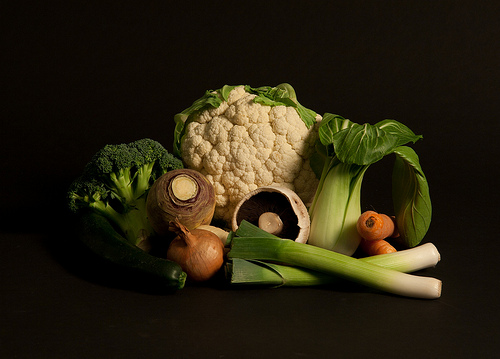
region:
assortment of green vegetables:
[43, 36, 468, 326]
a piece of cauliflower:
[168, 74, 325, 207]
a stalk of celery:
[236, 214, 446, 302]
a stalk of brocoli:
[62, 140, 187, 253]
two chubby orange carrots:
[356, 200, 398, 259]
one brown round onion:
[159, 212, 224, 293]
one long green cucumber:
[46, 209, 201, 311]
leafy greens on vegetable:
[316, 110, 441, 250]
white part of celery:
[389, 238, 456, 305]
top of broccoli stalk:
[68, 135, 178, 180]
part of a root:
[404, 290, 411, 295]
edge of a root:
[316, 216, 328, 249]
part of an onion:
[206, 256, 218, 263]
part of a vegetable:
[400, 182, 407, 200]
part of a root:
[201, 158, 220, 191]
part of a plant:
[320, 180, 332, 197]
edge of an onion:
[202, 255, 209, 263]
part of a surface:
[241, 314, 260, 324]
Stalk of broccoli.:
[63, 137, 195, 283]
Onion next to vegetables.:
[164, 217, 226, 284]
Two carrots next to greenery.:
[355, 200, 400, 262]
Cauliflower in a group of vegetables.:
[174, 88, 314, 208]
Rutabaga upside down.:
[154, 165, 223, 242]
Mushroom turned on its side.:
[233, 177, 315, 256]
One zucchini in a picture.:
[73, 185, 194, 293]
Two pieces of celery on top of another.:
[231, 221, 450, 305]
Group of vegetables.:
[44, 88, 449, 304]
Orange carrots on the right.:
[358, 193, 429, 276]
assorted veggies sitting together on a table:
[51, 82, 447, 309]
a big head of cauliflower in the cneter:
[174, 88, 311, 202]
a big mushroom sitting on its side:
[232, 183, 309, 248]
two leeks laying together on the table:
[218, 224, 443, 305]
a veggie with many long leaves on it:
[308, 108, 426, 263]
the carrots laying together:
[357, 209, 405, 258]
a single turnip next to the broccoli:
[150, 170, 212, 222]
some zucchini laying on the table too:
[73, 193, 189, 288]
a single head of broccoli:
[62, 133, 178, 240]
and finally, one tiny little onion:
[161, 223, 226, 273]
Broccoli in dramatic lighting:
[70, 147, 177, 235]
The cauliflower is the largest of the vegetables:
[165, 87, 327, 212]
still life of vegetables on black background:
[35, 50, 479, 344]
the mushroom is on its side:
[230, 184, 314, 246]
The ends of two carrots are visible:
[355, 200, 396, 260]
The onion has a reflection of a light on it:
[155, 211, 230, 281]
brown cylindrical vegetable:
[147, 168, 220, 230]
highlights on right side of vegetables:
[287, 67, 454, 313]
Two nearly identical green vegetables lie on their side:
[224, 215, 456, 312]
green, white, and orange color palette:
[70, 76, 449, 313]